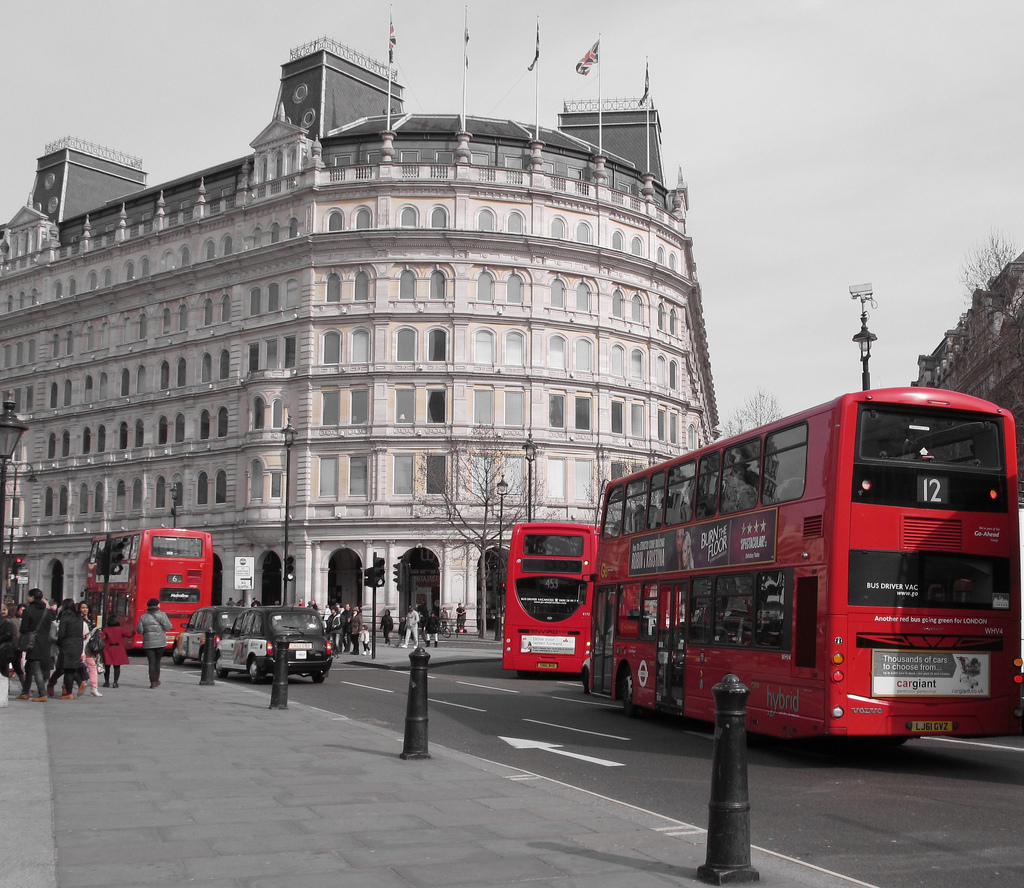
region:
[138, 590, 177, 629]
the head of a woman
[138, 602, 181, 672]
the back of a woman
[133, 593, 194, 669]
a woman wearing a jacket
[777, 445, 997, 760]
the back of a bus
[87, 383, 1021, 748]
the buses are red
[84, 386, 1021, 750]
the buses are double deckers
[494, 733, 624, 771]
the painted arrow is white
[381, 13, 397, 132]
the flag is on the pole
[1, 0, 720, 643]
the flags on the building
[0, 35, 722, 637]
the building has a lot of windows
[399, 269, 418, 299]
the window is arched at the top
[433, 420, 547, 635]
the tree is bare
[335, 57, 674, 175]
Flagpoles on top of building.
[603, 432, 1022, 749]
Red double decker bus.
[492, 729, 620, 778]
White arrow painted on street.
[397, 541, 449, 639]
A building's arched entryway.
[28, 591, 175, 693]
People walking on sidewalk.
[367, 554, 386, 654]
A traffic signal on pole.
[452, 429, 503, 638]
Tall tree with no leaves.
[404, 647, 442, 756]
Metal barrier post.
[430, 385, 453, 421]
Dark, rectangular window on building.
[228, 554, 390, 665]
A white sign above sidewalk.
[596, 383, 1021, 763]
the double decker bus is red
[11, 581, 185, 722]
a group of people on the sidewalk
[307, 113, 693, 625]
the side of the building is curved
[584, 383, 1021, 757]
red double decker bus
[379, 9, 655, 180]
five flagpoles with flags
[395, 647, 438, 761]
black post in the sidewalk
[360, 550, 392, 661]
black traffic light on the median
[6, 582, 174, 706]
people walking on the sidewalk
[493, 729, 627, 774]
white arrow on the street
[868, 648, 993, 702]
white and gray sign on the bus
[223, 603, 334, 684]
black and white car on the street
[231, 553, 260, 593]
black and white street sign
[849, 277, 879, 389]
black street light with an antenna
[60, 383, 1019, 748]
red double decker buses on the road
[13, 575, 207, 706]
people on the left side sidewalk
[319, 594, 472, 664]
people in front of the white building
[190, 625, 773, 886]
black pillars on the sidewalk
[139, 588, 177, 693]
person wearing gray puffy jacket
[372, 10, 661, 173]
flag poles attached to the building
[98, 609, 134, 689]
person wearing long red coat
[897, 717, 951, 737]
yellow license plate with black lettering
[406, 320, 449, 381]
a window on the building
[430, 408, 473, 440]
a window on the building